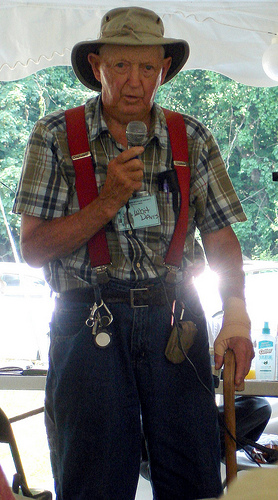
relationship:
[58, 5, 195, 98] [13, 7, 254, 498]
green hat on man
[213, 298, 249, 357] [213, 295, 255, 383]
bandage on mans hand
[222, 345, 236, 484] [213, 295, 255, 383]
cane in mans hand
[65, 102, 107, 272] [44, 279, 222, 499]
red suspender on mans pants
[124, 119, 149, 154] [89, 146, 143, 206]
microphone in mans hand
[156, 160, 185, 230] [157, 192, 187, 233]
glasses case in pocket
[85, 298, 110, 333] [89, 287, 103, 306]
key ring on belt loop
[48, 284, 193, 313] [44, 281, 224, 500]
black belt on blue jeans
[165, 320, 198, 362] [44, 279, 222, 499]
case hanging from pants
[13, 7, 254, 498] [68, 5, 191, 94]
man in a green hat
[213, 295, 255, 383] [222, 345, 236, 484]
hand holding cane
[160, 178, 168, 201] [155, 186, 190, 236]
pen in pocket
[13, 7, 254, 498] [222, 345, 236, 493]
man holding cane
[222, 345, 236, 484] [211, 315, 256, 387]
cane in hand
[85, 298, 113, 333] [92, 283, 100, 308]
key ring hanging from hoop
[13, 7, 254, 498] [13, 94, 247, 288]
man wearing shirt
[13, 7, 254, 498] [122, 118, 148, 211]
man holding microphone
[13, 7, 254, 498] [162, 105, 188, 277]
man wearing suspenders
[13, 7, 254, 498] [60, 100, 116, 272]
man wearing suspenders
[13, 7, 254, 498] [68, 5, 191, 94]
man wearing green hat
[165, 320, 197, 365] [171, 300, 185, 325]
case hanging from case handing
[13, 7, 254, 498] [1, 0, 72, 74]
man under tent